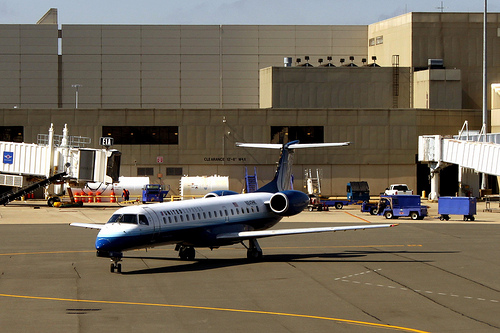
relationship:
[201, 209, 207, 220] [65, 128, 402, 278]
window on a plane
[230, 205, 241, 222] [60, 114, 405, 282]
window on a plane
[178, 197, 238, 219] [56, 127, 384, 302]
window on a plane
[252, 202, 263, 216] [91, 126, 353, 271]
window on a plane